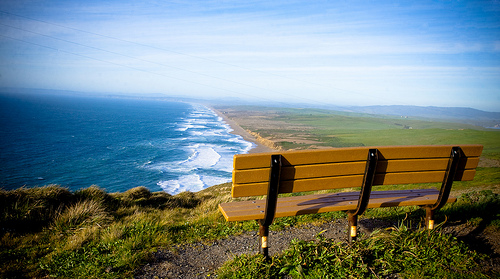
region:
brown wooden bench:
[225, 141, 472, 209]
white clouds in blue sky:
[14, 14, 87, 58]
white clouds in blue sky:
[19, 35, 72, 63]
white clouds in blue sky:
[71, 19, 145, 55]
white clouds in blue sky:
[73, 55, 141, 78]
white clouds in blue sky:
[144, 17, 174, 39]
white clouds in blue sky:
[173, 36, 230, 82]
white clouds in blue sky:
[216, 12, 289, 58]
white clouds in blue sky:
[282, 43, 347, 96]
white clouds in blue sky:
[346, 43, 457, 119]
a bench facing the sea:
[199, 132, 476, 242]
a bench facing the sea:
[149, 77, 471, 277]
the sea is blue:
[38, 90, 110, 174]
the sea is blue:
[82, 121, 186, 193]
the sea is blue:
[104, 111, 223, 186]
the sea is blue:
[72, 96, 158, 163]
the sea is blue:
[42, 108, 172, 176]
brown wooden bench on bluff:
[219, 137, 479, 238]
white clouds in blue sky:
[27, 21, 61, 47]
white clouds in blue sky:
[103, 43, 141, 77]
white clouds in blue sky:
[134, 17, 227, 77]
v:
[191, 47, 248, 91]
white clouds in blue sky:
[323, 27, 426, 68]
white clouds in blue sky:
[369, 56, 448, 102]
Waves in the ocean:
[138, 98, 253, 194]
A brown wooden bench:
[219, 142, 483, 262]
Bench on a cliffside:
[1, 140, 498, 277]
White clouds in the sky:
[1, 1, 498, 110]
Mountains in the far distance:
[206, 96, 499, 121]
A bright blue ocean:
[0, 91, 253, 194]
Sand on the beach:
[210, 102, 274, 155]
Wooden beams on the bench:
[230, 142, 484, 198]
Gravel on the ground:
[133, 212, 401, 277]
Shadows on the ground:
[360, 198, 499, 261]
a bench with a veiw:
[220, 125, 498, 248]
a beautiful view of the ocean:
[18, 71, 281, 211]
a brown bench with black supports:
[193, 125, 465, 277]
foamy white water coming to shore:
[172, 88, 263, 207]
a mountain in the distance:
[295, 88, 497, 124]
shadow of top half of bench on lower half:
[301, 183, 456, 217]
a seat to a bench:
[221, 179, 459, 224]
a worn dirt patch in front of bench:
[173, 211, 443, 277]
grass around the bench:
[26, 173, 478, 271]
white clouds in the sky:
[58, 14, 465, 107]